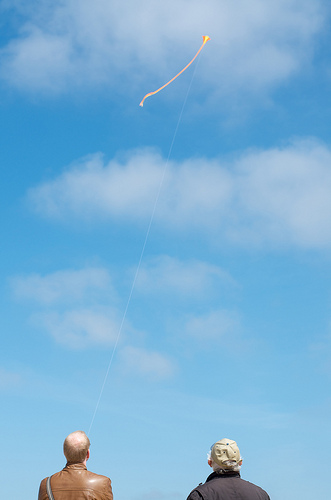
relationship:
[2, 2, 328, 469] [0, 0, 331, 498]
clouds in sky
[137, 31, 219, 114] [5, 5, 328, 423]
kite flying in air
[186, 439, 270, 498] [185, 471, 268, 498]
man wearing coat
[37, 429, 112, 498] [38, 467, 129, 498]
man wearing coat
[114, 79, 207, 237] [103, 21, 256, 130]
string connected to kite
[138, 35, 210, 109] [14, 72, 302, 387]
kite flies in sky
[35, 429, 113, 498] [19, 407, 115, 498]
gentleman wearing jacket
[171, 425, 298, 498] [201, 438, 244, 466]
gentleman wearing hat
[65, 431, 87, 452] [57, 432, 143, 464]
bald spot on head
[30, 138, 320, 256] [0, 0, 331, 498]
clouds in sky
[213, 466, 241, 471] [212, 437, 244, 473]
hair under hat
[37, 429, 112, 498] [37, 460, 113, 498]
man wearing jacket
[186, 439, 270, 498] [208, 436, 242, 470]
man wearing hat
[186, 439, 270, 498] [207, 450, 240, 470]
man has hair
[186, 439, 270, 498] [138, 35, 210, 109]
man watching kite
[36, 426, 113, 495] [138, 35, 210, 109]
man watching kite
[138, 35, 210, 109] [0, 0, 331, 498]
kite in sky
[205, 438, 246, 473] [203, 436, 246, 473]
hat on head